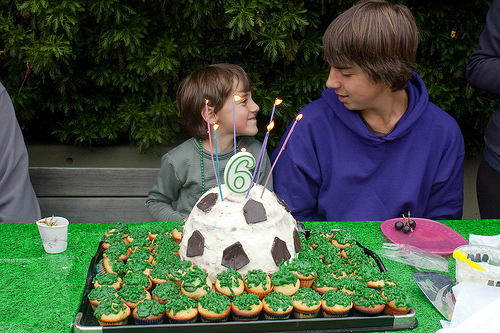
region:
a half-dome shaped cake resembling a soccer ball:
[180, 182, 300, 267]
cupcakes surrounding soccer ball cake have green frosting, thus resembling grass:
[87, 221, 405, 316]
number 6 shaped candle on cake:
[216, 136, 251, 191]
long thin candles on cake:
[190, 85, 295, 215]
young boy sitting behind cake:
[145, 57, 295, 243]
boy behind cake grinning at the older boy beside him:
[170, 42, 380, 154]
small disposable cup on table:
[25, 207, 70, 257]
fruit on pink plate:
[375, 198, 455, 263]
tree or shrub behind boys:
[0, 5, 495, 150]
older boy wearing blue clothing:
[276, 64, 464, 228]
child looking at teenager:
[148, 2, 469, 212]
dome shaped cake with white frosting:
[170, 165, 307, 270]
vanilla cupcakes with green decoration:
[140, 261, 310, 311]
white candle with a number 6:
[217, 141, 257, 196]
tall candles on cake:
[195, 86, 296, 216]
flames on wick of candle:
[260, 87, 290, 132]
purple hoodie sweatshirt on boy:
[287, 75, 468, 220]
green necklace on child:
[190, 140, 206, 196]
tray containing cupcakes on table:
[324, 288, 416, 328]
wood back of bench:
[60, 162, 144, 210]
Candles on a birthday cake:
[179, 93, 304, 208]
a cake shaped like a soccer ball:
[174, 177, 302, 267]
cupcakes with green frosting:
[110, 260, 194, 317]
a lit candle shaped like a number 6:
[223, 137, 258, 192]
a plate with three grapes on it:
[379, 207, 455, 257]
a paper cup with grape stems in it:
[36, 208, 74, 253]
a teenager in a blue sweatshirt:
[289, 31, 487, 206]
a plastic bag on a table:
[381, 240, 448, 277]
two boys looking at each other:
[131, 32, 468, 219]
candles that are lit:
[269, 81, 306, 139]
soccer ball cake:
[145, 130, 332, 301]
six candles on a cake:
[202, 120, 285, 207]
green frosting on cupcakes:
[110, 277, 300, 331]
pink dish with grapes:
[382, 210, 450, 255]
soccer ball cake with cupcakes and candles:
[155, 88, 356, 268]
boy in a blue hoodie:
[306, 41, 458, 196]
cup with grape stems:
[29, 207, 85, 285]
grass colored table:
[12, 260, 62, 298]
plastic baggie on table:
[375, 237, 465, 292]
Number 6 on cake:
[220, 143, 258, 194]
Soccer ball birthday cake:
[187, 185, 293, 264]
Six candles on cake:
[181, 90, 303, 196]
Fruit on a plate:
[393, 211, 420, 232]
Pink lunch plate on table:
[376, 217, 465, 254]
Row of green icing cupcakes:
[94, 282, 394, 317]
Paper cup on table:
[34, 215, 81, 258]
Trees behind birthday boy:
[26, 26, 159, 133]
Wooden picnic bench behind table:
[42, 168, 149, 213]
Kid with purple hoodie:
[314, 106, 475, 207]